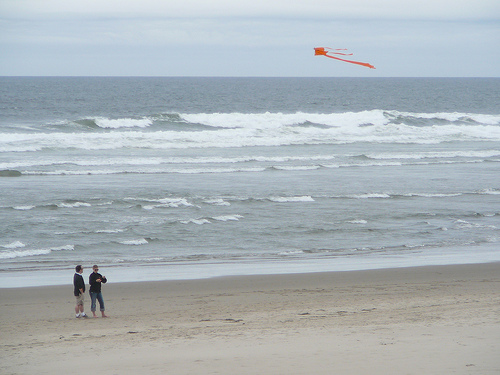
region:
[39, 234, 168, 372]
two people standing on the beach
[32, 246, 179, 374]
two people standing on the sand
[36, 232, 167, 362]
two people standing togehter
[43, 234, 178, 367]
two people standing together on the beach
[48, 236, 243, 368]
two people standing together on the sand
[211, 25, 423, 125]
a kite flying in the sky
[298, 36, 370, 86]
a kite flying in the sky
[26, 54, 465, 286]
a body of water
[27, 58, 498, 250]
a body of water with waves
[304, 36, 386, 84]
Small orange kite in the air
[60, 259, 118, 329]
Two people standing on the beach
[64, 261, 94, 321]
Man with dark hair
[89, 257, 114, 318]
Woman with dark hair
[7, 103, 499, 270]
Waves in the ocean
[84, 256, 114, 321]
Woman with black sweater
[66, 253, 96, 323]
Man with white socks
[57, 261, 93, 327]
man with khaki shorts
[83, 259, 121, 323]
Woman with dark glasses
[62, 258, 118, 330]
Couple flying a kite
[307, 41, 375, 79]
red kite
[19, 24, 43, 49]
white clouds in blue sky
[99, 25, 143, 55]
white clouds in blue sky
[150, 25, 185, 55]
white clouds in blue sky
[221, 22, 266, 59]
white clouds in blue sky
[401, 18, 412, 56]
white clouds in blue sky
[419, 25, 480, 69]
white clouds in blue sky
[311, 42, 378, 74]
An orange kite with tails in action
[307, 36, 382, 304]
An orange kite in action over the beach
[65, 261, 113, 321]
A casually dressed couple at the beach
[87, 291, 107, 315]
A pair of blue jean capris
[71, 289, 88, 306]
A pair of mens khaki cargo shorts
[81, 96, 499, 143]
A wave coming into shore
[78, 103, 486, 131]
Crest of a wave coming into shore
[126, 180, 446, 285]
Choppy water and waves heading to shore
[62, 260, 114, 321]
A casually dressed couple having an active discussion on a beach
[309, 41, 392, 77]
Orange kite in action with one long tail and two shorter tails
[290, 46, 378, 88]
orange kite in air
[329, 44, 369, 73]
kite has orange streamers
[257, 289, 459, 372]
sand is light brown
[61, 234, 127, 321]
two people on beach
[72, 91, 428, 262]
water is white and choppy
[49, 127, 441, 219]
heavy waves on water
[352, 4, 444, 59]
sky is blue and grey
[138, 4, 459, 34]
thick clouds in sky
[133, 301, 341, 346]
few tracks on sand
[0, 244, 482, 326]
water flows onto beach